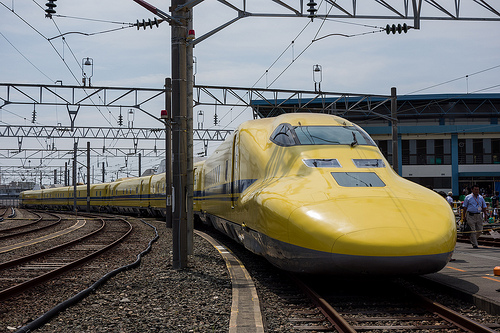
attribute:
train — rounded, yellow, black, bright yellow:
[18, 108, 458, 276]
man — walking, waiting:
[460, 184, 491, 245]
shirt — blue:
[461, 191, 489, 216]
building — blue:
[254, 83, 498, 220]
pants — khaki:
[464, 211, 486, 246]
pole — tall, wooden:
[162, 4, 200, 274]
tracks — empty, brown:
[4, 207, 496, 332]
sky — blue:
[4, 5, 499, 193]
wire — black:
[57, 8, 139, 29]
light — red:
[160, 108, 168, 121]